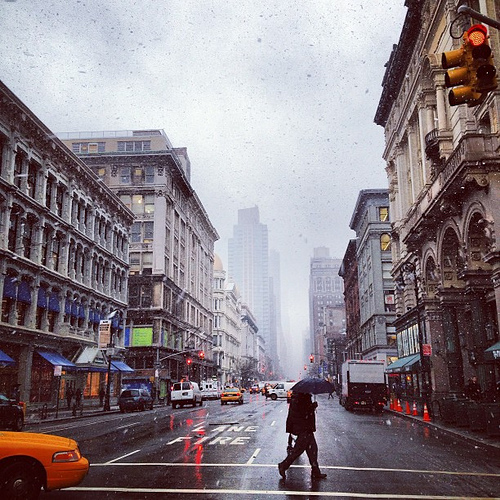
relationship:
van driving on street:
[169, 380, 203, 407] [4, 380, 499, 498]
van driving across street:
[263, 380, 299, 400] [4, 380, 499, 498]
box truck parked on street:
[337, 358, 390, 414] [4, 380, 499, 498]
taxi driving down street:
[0, 427, 90, 499] [4, 380, 499, 498]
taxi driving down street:
[220, 385, 243, 405] [4, 380, 499, 498]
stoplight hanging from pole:
[458, 23, 498, 93] [456, 4, 500, 32]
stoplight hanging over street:
[458, 23, 498, 93] [4, 380, 499, 498]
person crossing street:
[276, 385, 327, 482] [4, 380, 499, 498]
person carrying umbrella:
[276, 385, 327, 482] [291, 375, 337, 397]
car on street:
[117, 385, 155, 412] [4, 380, 499, 498]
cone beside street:
[388, 395, 395, 411] [4, 380, 499, 498]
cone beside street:
[395, 397, 403, 413] [4, 380, 499, 498]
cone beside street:
[404, 399, 412, 413] [4, 380, 499, 498]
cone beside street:
[410, 401, 420, 417] [4, 380, 499, 498]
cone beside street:
[421, 403, 431, 423] [4, 380, 499, 498]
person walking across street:
[276, 385, 327, 482] [4, 380, 499, 498]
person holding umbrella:
[276, 385, 327, 482] [291, 375, 337, 397]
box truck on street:
[337, 358, 390, 414] [4, 380, 499, 498]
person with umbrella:
[276, 385, 327, 482] [291, 375, 337, 397]